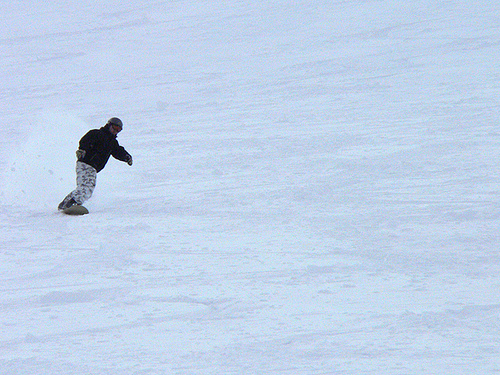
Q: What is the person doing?
A: Snowboarding.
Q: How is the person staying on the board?
A: His feet are attached to it.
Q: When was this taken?
A: During the day.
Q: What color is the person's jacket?
A: Black.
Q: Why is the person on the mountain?
A: They are there to snowboard.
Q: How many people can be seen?
A: One.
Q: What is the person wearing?
A: Snow pants and a jacket.